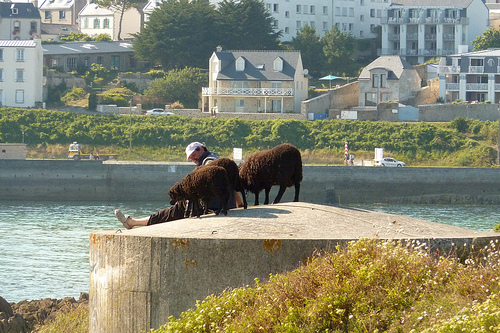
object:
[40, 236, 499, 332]
grass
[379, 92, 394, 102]
window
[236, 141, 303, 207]
sheep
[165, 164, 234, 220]
sheep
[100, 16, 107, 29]
window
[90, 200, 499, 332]
ledge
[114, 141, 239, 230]
man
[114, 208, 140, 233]
shoe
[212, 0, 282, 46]
trees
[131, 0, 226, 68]
trees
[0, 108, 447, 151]
bushes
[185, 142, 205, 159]
hat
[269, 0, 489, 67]
building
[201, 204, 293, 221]
shadow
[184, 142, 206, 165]
head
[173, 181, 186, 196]
neck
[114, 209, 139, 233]
foot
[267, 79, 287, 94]
window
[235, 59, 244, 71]
window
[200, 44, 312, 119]
building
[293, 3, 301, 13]
window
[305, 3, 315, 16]
window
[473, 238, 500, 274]
flowers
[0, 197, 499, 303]
water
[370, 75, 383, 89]
glass window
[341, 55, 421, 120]
building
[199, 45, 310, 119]
house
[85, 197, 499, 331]
cement pier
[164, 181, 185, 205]
head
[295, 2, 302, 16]
window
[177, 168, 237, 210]
fur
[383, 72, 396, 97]
window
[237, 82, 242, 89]
window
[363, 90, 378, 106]
window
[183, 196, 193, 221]
leg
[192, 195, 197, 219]
leg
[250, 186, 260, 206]
leg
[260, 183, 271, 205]
leg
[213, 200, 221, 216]
leg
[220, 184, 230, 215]
leg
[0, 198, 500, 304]
river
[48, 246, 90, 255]
ripple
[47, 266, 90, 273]
ripple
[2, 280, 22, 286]
ripple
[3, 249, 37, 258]
ripple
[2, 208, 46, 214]
ripple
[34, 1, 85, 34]
building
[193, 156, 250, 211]
sheep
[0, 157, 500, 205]
pier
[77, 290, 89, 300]
rock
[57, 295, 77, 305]
rock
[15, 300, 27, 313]
rock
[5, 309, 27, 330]
rock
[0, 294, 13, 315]
rock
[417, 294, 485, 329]
weed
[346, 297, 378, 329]
weed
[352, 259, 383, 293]
weed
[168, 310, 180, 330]
weed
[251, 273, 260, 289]
weed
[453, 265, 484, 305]
brush